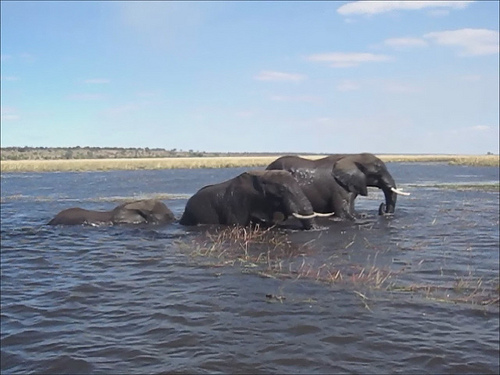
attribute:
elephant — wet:
[175, 167, 337, 230]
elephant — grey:
[194, 130, 419, 249]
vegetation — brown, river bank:
[4, 156, 499, 171]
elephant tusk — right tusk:
[386, 187, 409, 197]